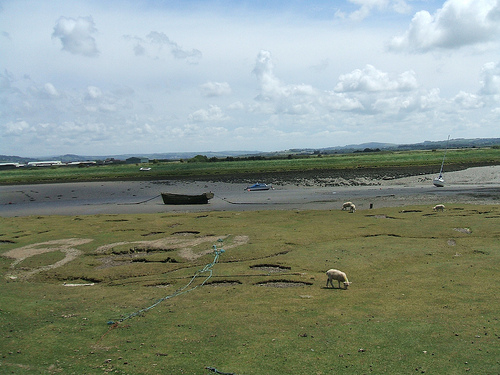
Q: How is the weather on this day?
A: It is cloudy.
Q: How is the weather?
A: It is cloudy.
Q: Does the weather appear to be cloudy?
A: Yes, it is cloudy.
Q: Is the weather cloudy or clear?
A: It is cloudy.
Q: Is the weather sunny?
A: No, it is cloudy.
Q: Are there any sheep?
A: Yes, there is a sheep.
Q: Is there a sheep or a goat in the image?
A: Yes, there is a sheep.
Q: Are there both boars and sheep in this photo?
A: No, there is a sheep but no boars.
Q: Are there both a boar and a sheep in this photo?
A: No, there is a sheep but no boars.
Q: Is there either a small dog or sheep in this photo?
A: Yes, there is a small sheep.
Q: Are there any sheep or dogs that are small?
A: Yes, the sheep is small.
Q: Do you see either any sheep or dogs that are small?
A: Yes, the sheep is small.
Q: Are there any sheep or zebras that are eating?
A: Yes, the sheep is eating.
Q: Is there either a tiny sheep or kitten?
A: Yes, there is a tiny sheep.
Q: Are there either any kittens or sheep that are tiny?
A: Yes, the sheep is tiny.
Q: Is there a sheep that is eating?
A: Yes, there is a sheep that is eating.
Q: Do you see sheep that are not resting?
A: Yes, there is a sheep that is eating .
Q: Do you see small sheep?
A: Yes, there is a small sheep.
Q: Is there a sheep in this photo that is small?
A: Yes, there is a sheep that is small.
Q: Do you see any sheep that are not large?
A: Yes, there is a small sheep.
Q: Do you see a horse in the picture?
A: No, there are no horses.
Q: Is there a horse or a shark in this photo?
A: No, there are no horses or sharks.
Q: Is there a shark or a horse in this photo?
A: No, there are no horses or sharks.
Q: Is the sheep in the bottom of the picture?
A: Yes, the sheep is in the bottom of the image.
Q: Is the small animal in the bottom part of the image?
A: Yes, the sheep is in the bottom of the image.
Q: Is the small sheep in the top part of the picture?
A: No, the sheep is in the bottom of the image.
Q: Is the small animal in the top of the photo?
A: No, the sheep is in the bottom of the image.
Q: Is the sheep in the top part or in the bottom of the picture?
A: The sheep is in the bottom of the image.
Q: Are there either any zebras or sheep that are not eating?
A: No, there is a sheep but it is eating.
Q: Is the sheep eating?
A: Yes, the sheep is eating.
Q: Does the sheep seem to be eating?
A: Yes, the sheep is eating.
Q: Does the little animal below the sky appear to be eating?
A: Yes, the sheep is eating.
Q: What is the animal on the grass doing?
A: The sheep is eating.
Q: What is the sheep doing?
A: The sheep is eating.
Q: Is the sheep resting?
A: No, the sheep is eating.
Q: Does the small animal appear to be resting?
A: No, the sheep is eating.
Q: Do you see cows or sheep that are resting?
A: No, there is a sheep but it is eating.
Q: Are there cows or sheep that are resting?
A: No, there is a sheep but it is eating.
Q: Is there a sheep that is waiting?
A: No, there is a sheep but it is eating.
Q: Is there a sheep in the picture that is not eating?
A: No, there is a sheep but it is eating.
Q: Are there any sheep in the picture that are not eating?
A: No, there is a sheep but it is eating.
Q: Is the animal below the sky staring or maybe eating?
A: The sheep is eating.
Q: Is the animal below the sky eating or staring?
A: The sheep is eating.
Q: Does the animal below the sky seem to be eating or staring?
A: The sheep is eating.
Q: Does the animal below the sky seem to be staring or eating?
A: The sheep is eating.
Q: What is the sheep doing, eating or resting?
A: The sheep is eating.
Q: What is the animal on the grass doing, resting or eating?
A: The sheep is eating.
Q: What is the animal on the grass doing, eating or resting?
A: The sheep is eating.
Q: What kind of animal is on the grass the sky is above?
A: The animal is a sheep.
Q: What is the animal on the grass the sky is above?
A: The animal is a sheep.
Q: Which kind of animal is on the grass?
A: The animal is a sheep.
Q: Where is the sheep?
A: The sheep is on the grass.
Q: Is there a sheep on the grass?
A: Yes, there is a sheep on the grass.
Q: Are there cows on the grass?
A: No, there is a sheep on the grass.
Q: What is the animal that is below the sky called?
A: The animal is a sheep.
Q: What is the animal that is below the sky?
A: The animal is a sheep.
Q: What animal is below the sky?
A: The animal is a sheep.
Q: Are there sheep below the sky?
A: Yes, there is a sheep below the sky.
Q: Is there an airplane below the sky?
A: No, there is a sheep below the sky.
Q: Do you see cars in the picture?
A: No, there are no cars.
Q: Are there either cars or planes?
A: No, there are no cars or planes.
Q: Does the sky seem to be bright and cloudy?
A: Yes, the sky is bright and cloudy.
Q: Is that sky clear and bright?
A: No, the sky is bright but cloudy.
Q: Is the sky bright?
A: Yes, the sky is bright.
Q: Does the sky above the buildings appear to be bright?
A: Yes, the sky is bright.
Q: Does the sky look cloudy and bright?
A: Yes, the sky is cloudy and bright.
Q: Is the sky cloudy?
A: Yes, the sky is cloudy.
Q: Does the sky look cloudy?
A: Yes, the sky is cloudy.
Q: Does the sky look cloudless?
A: No, the sky is cloudy.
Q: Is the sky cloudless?
A: No, the sky is cloudy.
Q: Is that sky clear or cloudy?
A: The sky is cloudy.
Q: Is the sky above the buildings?
A: Yes, the sky is above the buildings.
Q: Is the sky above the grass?
A: Yes, the sky is above the grass.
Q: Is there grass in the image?
A: Yes, there is grass.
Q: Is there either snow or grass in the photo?
A: Yes, there is grass.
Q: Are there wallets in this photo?
A: No, there are no wallets.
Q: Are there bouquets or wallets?
A: No, there are no wallets or bouquets.